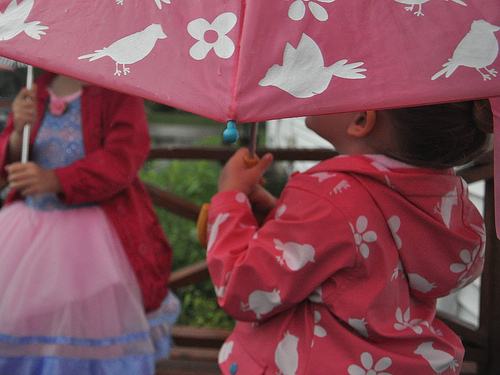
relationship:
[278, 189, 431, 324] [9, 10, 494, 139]
jacket and umbrella